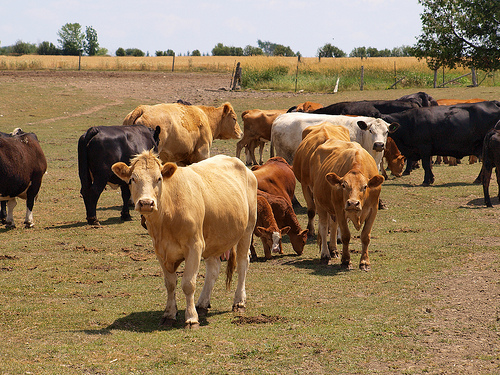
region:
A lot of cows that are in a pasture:
[13, 75, 448, 277]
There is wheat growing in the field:
[122, 44, 360, 75]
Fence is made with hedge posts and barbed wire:
[68, 47, 245, 82]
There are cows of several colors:
[70, 96, 420, 277]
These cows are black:
[391, 97, 498, 203]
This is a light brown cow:
[314, 140, 394, 285]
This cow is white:
[357, 122, 393, 155]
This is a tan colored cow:
[115, 139, 262, 327]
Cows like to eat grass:
[112, 82, 411, 322]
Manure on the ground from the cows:
[111, 242, 149, 287]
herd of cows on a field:
[1, 86, 429, 350]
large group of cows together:
[7, 43, 408, 290]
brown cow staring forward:
[103, 145, 265, 331]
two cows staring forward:
[295, 116, 395, 267]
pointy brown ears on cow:
[112, 149, 186, 181]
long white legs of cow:
[72, 240, 282, 325]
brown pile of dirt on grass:
[212, 305, 290, 342]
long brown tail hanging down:
[210, 252, 237, 294]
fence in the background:
[205, 56, 382, 91]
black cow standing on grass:
[64, 125, 156, 217]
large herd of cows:
[0, 79, 474, 304]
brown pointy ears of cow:
[102, 160, 184, 181]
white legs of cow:
[137, 262, 258, 339]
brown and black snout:
[135, 194, 155, 213]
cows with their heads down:
[248, 168, 303, 259]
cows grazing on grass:
[247, 188, 305, 262]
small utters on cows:
[106, 182, 121, 190]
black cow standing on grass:
[75, 118, 169, 185]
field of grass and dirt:
[10, 240, 115, 368]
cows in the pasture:
[8, 88, 498, 330]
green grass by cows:
[285, 293, 360, 344]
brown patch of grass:
[446, 257, 486, 364]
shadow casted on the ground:
[94, 300, 171, 349]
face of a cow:
[111, 146, 183, 210]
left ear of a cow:
[361, 170, 386, 194]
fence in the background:
[28, 46, 305, 78]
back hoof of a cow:
[227, 303, 249, 318]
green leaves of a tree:
[421, 1, 498, 67]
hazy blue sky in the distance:
[111, 7, 397, 41]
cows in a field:
[10, 61, 497, 340]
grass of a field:
[282, 272, 388, 338]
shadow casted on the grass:
[84, 298, 167, 349]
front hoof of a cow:
[181, 311, 206, 338]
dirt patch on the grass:
[81, 76, 184, 97]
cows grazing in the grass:
[255, 217, 321, 271]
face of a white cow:
[354, 114, 397, 153]